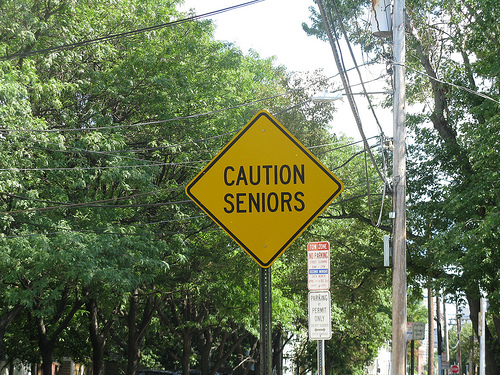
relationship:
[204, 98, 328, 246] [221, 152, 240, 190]
sign has letter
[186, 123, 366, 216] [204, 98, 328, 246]
letting on sign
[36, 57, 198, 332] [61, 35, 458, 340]
tree in distance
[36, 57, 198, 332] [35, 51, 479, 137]
tree in background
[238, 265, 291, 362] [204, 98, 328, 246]
pole on sign